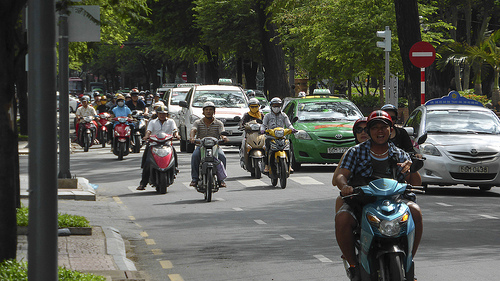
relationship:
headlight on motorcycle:
[378, 219, 400, 236] [339, 179, 425, 279]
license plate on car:
[325, 147, 351, 153] [282, 93, 365, 169]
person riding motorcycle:
[260, 97, 299, 175] [261, 124, 298, 188]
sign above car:
[421, 89, 483, 106] [403, 102, 499, 190]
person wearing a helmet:
[260, 97, 299, 175] [269, 96, 284, 110]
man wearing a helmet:
[188, 100, 227, 188] [200, 100, 216, 110]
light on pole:
[375, 24, 394, 54] [383, 51, 391, 105]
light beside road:
[375, 24, 394, 54] [69, 114, 497, 279]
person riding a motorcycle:
[334, 107, 424, 280] [339, 179, 425, 279]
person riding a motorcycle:
[260, 97, 299, 175] [261, 124, 298, 188]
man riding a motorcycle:
[188, 100, 227, 188] [188, 136, 227, 203]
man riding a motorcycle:
[135, 107, 181, 190] [141, 132, 179, 195]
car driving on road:
[282, 93, 365, 169] [69, 114, 497, 279]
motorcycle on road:
[339, 179, 425, 279] [69, 114, 497, 279]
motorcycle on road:
[261, 124, 298, 188] [69, 114, 497, 279]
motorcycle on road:
[188, 136, 227, 203] [69, 114, 497, 279]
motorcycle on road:
[141, 132, 179, 195] [69, 114, 497, 279]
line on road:
[109, 196, 186, 279] [69, 114, 497, 279]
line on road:
[180, 177, 332, 266] [69, 114, 497, 279]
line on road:
[433, 201, 497, 220] [69, 114, 497, 279]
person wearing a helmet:
[334, 107, 424, 280] [367, 109, 394, 125]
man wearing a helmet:
[135, 107, 181, 190] [155, 104, 170, 114]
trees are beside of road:
[67, 1, 450, 114] [69, 114, 497, 279]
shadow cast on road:
[223, 183, 279, 193] [69, 114, 497, 279]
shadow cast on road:
[151, 196, 215, 207] [69, 114, 497, 279]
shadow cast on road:
[98, 189, 174, 199] [69, 114, 497, 279]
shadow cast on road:
[223, 173, 256, 181] [69, 114, 497, 279]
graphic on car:
[312, 121, 351, 133] [282, 93, 365, 169]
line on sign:
[410, 51, 434, 57] [408, 40, 437, 68]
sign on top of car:
[310, 86, 332, 98] [282, 93, 365, 169]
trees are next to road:
[67, 1, 450, 114] [69, 114, 497, 279]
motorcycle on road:
[228, 115, 267, 180] [69, 114, 497, 279]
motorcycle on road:
[104, 114, 133, 160] [69, 114, 497, 279]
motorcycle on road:
[71, 115, 98, 153] [69, 114, 497, 279]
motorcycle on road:
[94, 110, 113, 148] [69, 114, 497, 279]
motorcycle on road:
[128, 110, 143, 153] [69, 114, 497, 279]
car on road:
[282, 93, 365, 169] [69, 114, 497, 279]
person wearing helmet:
[334, 107, 424, 280] [367, 109, 394, 125]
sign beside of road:
[408, 40, 437, 68] [69, 114, 497, 279]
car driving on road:
[403, 102, 499, 190] [69, 114, 497, 279]